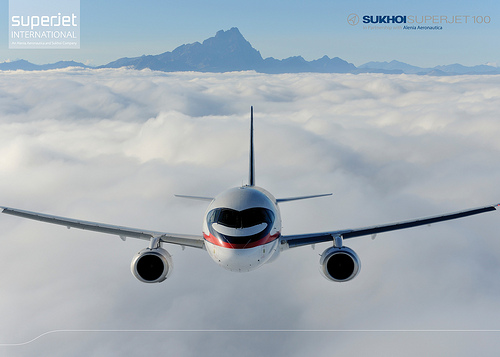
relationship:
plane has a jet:
[1, 104, 500, 283] [131, 246, 174, 284]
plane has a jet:
[1, 104, 500, 283] [316, 247, 361, 283]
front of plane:
[201, 207, 282, 249] [1, 104, 500, 283]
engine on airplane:
[131, 246, 174, 284] [1, 104, 500, 283]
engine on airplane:
[316, 247, 361, 283] [1, 104, 500, 283]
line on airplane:
[200, 232, 279, 249] [1, 104, 500, 283]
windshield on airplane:
[207, 205, 276, 229] [1, 104, 500, 283]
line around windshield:
[207, 207, 276, 245] [207, 205, 276, 229]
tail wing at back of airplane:
[273, 191, 337, 204] [1, 104, 500, 283]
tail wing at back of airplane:
[173, 191, 214, 200] [1, 104, 500, 283]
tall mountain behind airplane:
[171, 26, 265, 70] [1, 104, 500, 283]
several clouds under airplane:
[0, 283, 497, 355] [1, 104, 500, 283]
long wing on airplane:
[279, 203, 499, 250] [1, 104, 500, 283]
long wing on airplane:
[0, 205, 207, 251] [1, 104, 500, 283]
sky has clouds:
[1, 0, 500, 164] [0, 73, 173, 204]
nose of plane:
[218, 232, 257, 265] [1, 104, 500, 283]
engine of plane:
[131, 246, 174, 284] [1, 104, 500, 283]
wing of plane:
[0, 205, 207, 251] [1, 104, 500, 283]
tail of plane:
[247, 102, 258, 190] [1, 104, 500, 283]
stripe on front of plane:
[200, 232, 279, 249] [1, 104, 500, 283]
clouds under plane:
[0, 283, 497, 355] [1, 104, 500, 283]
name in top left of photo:
[361, 13, 470, 26] [1, 2, 498, 356]